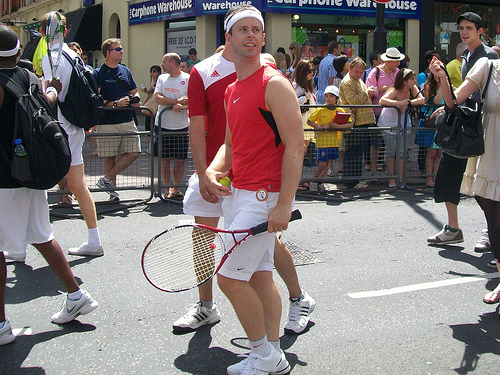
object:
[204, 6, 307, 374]
player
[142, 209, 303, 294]
tennis racket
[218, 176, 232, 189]
tennis ball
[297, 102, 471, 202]
barrier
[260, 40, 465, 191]
crowd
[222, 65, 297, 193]
shirt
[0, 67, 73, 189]
backpack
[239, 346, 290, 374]
shoe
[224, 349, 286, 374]
shoe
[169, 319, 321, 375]
shadow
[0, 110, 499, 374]
street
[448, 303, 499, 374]
shadow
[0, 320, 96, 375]
shadow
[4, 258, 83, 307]
shadow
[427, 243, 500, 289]
shadow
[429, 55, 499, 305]
woman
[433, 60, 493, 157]
purse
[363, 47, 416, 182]
man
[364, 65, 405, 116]
shirt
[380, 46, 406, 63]
hat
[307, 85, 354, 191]
boy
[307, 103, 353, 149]
shirt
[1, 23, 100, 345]
player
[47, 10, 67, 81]
tennis racket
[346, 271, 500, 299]
stripe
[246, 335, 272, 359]
socks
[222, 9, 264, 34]
sweatband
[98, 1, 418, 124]
building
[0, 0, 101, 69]
building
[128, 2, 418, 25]
sign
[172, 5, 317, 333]
man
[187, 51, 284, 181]
shirt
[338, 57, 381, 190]
person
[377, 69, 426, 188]
person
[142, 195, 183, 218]
shadow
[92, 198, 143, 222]
shadow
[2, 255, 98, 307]
shadow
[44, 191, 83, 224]
shadow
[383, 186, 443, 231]
shadow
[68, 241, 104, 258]
shoe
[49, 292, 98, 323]
shoe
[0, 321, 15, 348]
shoe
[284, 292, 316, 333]
shoe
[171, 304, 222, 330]
shoe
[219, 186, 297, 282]
shorts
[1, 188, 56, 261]
shorts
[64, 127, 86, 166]
shorts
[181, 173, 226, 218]
shorts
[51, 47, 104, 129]
backpack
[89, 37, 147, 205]
man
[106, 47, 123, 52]
sunglasses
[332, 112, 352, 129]
book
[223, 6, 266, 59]
head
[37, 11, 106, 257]
man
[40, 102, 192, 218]
barrier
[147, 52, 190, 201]
man